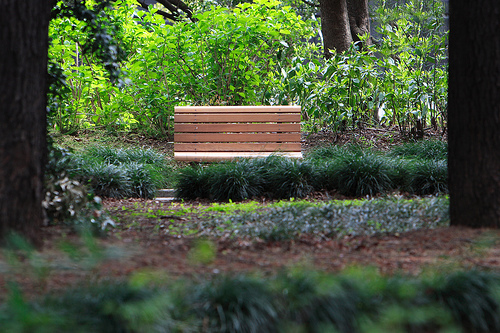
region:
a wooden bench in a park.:
[163, 79, 318, 191]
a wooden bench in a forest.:
[166, 83, 320, 165]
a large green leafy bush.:
[99, 0, 300, 100]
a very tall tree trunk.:
[0, 2, 67, 253]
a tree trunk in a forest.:
[444, 5, 499, 245]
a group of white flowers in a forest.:
[38, 161, 141, 263]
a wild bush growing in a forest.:
[52, 120, 183, 210]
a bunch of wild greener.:
[101, 14, 395, 107]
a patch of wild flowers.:
[61, 199, 446, 233]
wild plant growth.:
[56, 131, 143, 245]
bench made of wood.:
[212, 112, 285, 139]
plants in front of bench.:
[264, 162, 376, 173]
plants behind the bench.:
[184, 34, 250, 75]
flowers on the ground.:
[312, 207, 377, 232]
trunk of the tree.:
[8, 15, 32, 187]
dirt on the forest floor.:
[364, 240, 451, 262]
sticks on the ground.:
[347, 126, 393, 140]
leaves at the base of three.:
[44, 180, 76, 217]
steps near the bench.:
[157, 185, 172, 207]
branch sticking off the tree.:
[304, 4, 318, 11]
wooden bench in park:
[149, 86, 334, 203]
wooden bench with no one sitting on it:
[135, 81, 319, 196]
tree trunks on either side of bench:
[4, 6, 489, 258]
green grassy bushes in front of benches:
[186, 146, 424, 200]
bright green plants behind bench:
[108, 0, 293, 116]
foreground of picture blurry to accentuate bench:
[37, 252, 491, 324]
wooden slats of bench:
[170, 86, 328, 168]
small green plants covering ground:
[185, 186, 447, 245]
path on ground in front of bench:
[334, 230, 462, 270]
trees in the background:
[292, 12, 377, 54]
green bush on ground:
[197, 189, 262, 217]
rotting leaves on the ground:
[235, 237, 441, 280]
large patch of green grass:
[83, 130, 173, 188]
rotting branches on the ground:
[77, 104, 164, 154]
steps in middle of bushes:
[141, 180, 198, 217]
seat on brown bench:
[164, 138, 323, 178]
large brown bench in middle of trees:
[148, 85, 335, 188]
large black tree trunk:
[306, 3, 401, 55]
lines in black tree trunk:
[14, 90, 61, 239]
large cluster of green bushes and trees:
[76, 4, 422, 149]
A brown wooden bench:
[167, 100, 309, 167]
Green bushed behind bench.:
[50, 3, 432, 121]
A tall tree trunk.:
[0, 0, 61, 250]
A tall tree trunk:
[437, 0, 497, 235]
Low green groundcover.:
[75, 143, 446, 196]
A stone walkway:
[102, 174, 208, 211]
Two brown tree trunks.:
[318, 1, 380, 75]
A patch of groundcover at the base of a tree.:
[40, 176, 120, 243]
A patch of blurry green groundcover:
[4, 273, 472, 332]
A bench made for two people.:
[168, 101, 307, 166]